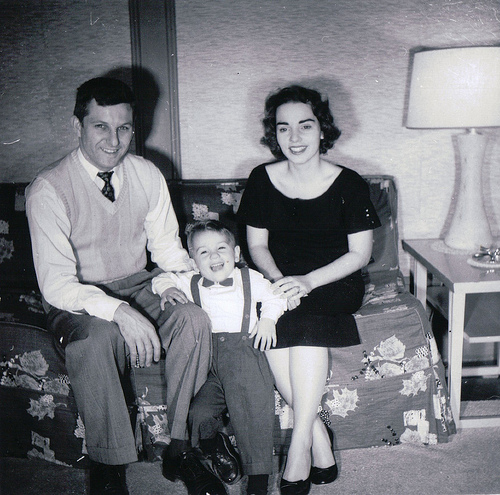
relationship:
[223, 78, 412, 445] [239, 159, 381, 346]
woman wearing dress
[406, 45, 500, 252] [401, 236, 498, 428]
lamp sitting on table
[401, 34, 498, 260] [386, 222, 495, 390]
lamp on a table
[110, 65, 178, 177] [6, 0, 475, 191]
shadow on wall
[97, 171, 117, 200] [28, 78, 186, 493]
tie on man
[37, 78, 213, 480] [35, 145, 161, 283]
man wearing sweater vest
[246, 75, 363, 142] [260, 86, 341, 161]
shadow on head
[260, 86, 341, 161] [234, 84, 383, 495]
head on woman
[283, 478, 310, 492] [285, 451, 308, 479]
shoe on foot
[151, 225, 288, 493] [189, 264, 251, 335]
boy wearing suspenders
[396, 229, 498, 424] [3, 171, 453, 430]
table next to couch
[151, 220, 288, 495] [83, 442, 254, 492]
boy wears shoes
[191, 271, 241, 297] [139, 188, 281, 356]
bowtie on boy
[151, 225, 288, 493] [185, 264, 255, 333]
boy wearing suspenders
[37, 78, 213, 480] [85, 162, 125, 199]
man wearing a neck tie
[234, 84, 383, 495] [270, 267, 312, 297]
woman has hand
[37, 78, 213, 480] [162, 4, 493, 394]
man on wall